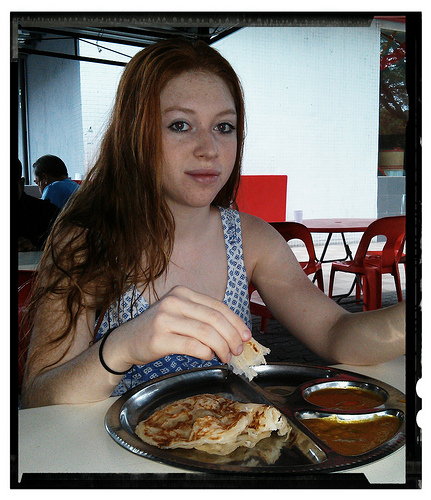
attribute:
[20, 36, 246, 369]
hair — long, red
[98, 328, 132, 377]
hair band — black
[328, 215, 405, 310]
chair — red, plastic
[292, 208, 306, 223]
cup — white, plastic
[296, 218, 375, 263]
table — red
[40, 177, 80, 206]
shirt — blue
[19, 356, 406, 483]
table — white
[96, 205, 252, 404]
blouse — blue, white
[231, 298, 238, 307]
design — small, blue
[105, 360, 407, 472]
tray — metal, silver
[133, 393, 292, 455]
bread — white, brown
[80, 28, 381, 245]
wall — white